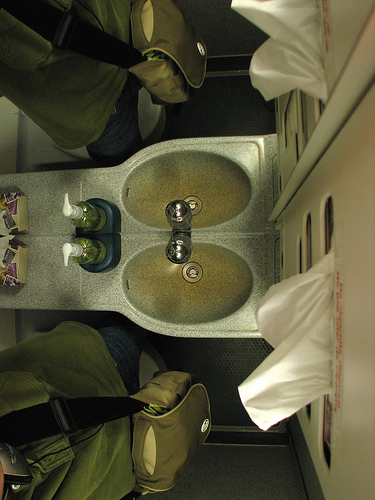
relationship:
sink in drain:
[114, 238, 258, 325] [181, 261, 202, 281]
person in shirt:
[0, 319, 170, 498] [2, 319, 135, 499]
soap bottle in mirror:
[42, 216, 126, 284] [65, 30, 269, 171]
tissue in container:
[235, 247, 339, 430] [269, 73, 374, 493]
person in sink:
[0, 319, 170, 498] [122, 242, 252, 325]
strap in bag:
[2, 4, 144, 69] [3, 3, 214, 111]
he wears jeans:
[8, 306, 185, 497] [72, 92, 147, 153]